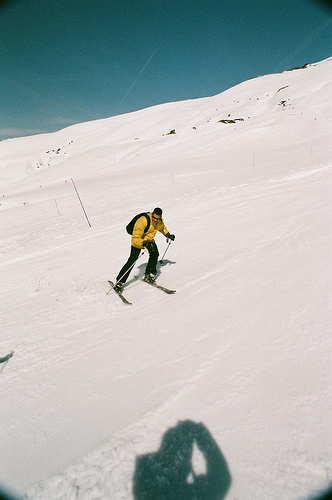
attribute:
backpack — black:
[126, 211, 151, 237]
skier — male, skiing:
[116, 207, 177, 295]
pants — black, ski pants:
[116, 241, 160, 281]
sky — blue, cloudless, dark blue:
[0, 2, 330, 143]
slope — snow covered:
[0, 55, 331, 498]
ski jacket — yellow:
[132, 213, 170, 249]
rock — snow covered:
[221, 119, 238, 124]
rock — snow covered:
[162, 127, 176, 135]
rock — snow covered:
[232, 117, 245, 122]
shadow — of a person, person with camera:
[132, 419, 232, 500]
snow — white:
[0, 56, 331, 499]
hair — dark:
[151, 207, 162, 214]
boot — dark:
[115, 282, 122, 293]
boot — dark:
[143, 274, 157, 285]